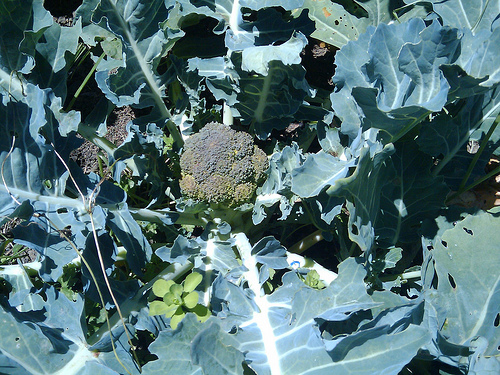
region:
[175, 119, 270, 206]
Small stalk of green broccoli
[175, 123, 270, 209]
A small head of broccoli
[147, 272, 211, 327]
A green leafy weed coming up through a broccoli leaf.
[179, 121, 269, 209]
A green stalk of broccoli in the middle.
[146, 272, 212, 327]
A green weed coming up through the broccoli leaves.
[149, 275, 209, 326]
Brighter green leaves on a weed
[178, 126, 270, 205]
A round piece of broccoli.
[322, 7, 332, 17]
An orange mark on a top leaf.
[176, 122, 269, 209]
A large round stalk of broccoli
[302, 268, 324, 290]
A green weed poking out to the bottom right of a broccoli.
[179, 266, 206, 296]
small green leaf on a plant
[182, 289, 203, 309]
small green leaf on a plant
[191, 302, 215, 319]
small green leaf on a plant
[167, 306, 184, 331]
small green leaf on a plant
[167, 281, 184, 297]
small green leaf on a plant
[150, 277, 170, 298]
small green leaf on a plant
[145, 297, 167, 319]
small green leaf on a plant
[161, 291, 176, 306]
small green leaf on a plant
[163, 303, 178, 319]
small green leaf on a plant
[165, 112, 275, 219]
small head of broccoli on a stalk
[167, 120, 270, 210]
broccoli beginning to grow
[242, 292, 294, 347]
bright sunlight shining on the leaf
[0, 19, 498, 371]
broccoli plant growing in the sun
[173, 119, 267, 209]
blue green broccoli head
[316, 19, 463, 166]
blue green broccoli plant leaf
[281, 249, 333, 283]
light green stem of a broccoli leaf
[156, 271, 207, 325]
a weed growing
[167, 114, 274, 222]
broccoli in the middle of a plant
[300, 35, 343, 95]
shade beneath broccoli leaves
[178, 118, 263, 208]
a head of brocolli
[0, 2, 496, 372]
a head of brocolli surrounded by leaves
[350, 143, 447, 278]
a leaf in the shade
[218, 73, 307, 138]
a leaf in the shade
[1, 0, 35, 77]
a leaf in the shade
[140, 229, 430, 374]
a leaf in the sunlight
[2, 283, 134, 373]
a leaf in the sunlight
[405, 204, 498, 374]
a leaf in the sunlight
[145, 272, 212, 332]
small green leaves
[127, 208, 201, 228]
the stem of a leaf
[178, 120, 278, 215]
a head of broccoli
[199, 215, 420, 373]
a large green leaf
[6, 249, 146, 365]
a large green leaf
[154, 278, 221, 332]
a large green leaf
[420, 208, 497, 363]
a large green leaf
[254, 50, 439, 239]
a large green leaf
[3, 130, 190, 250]
a large green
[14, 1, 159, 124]
a large green leaf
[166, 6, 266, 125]
a large green leaf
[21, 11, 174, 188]
Patch of green vegetation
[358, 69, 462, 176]
Patch of green vegetation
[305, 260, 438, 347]
Patch of green vegetation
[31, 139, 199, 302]
Patch of green vegetation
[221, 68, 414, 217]
Patch of green vegetation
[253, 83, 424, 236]
Patch of green vegetation